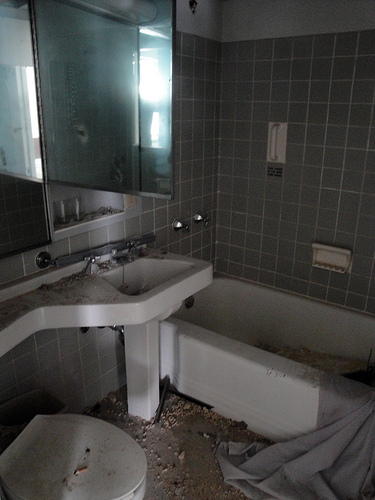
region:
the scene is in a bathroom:
[31, 25, 372, 496]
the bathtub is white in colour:
[224, 279, 308, 438]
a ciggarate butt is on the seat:
[61, 465, 108, 483]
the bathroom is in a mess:
[36, 235, 302, 481]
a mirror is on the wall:
[38, 33, 179, 214]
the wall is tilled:
[186, 57, 362, 105]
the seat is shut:
[27, 412, 193, 498]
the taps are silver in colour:
[67, 240, 169, 267]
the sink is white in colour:
[22, 269, 203, 410]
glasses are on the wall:
[40, 184, 157, 241]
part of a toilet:
[128, 482, 137, 491]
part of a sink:
[140, 351, 148, 369]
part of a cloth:
[288, 456, 292, 462]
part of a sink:
[50, 303, 63, 323]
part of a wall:
[303, 277, 311, 294]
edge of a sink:
[151, 391, 172, 410]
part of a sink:
[234, 377, 250, 402]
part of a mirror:
[64, 309, 71, 321]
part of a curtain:
[270, 438, 279, 462]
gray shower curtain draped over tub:
[212, 361, 373, 497]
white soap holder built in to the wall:
[311, 242, 351, 273]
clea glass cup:
[53, 198, 71, 223]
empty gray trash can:
[2, 388, 71, 440]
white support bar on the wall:
[267, 120, 287, 164]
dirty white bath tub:
[159, 271, 372, 453]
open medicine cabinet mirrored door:
[30, 0, 174, 198]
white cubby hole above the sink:
[45, 181, 140, 239]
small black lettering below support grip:
[265, 164, 282, 178]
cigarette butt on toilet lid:
[74, 465, 87, 474]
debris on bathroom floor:
[87, 380, 268, 498]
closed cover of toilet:
[1, 411, 147, 498]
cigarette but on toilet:
[73, 465, 88, 475]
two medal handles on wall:
[172, 211, 209, 231]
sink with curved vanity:
[1, 240, 213, 353]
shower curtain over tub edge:
[215, 371, 373, 498]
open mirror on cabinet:
[35, 0, 178, 238]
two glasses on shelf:
[54, 195, 84, 225]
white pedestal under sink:
[125, 317, 163, 419]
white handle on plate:
[265, 120, 286, 165]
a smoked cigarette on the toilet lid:
[28, 435, 115, 490]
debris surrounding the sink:
[83, 352, 261, 496]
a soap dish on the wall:
[304, 236, 359, 279]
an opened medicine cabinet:
[0, 0, 169, 239]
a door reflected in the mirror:
[6, 66, 46, 186]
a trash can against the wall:
[3, 389, 73, 425]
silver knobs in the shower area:
[169, 211, 225, 239]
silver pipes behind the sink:
[96, 321, 162, 342]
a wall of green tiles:
[212, 40, 372, 310]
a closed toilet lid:
[14, 422, 149, 497]